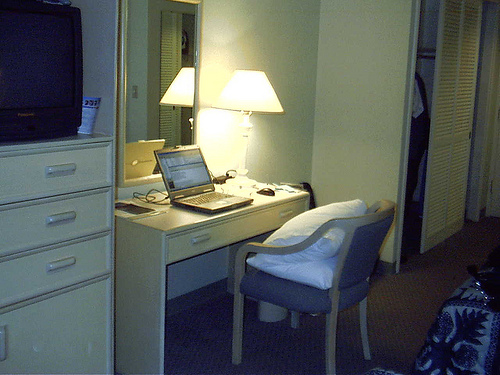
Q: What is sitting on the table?
A: Lamp.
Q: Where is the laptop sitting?
A: Table.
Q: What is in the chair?
A: Pillows.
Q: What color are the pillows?
A: White.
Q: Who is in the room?
A: No one.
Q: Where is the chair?
A: Near the table.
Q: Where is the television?
A: On the television stand.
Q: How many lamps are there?
A: One.